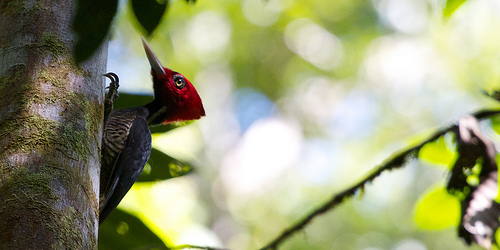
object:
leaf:
[132, 148, 198, 183]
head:
[133, 36, 206, 122]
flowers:
[440, 113, 499, 196]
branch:
[262, 107, 499, 250]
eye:
[172, 75, 185, 89]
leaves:
[411, 129, 499, 175]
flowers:
[458, 168, 499, 250]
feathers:
[96, 106, 149, 201]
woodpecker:
[95, 36, 208, 228]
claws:
[97, 73, 124, 97]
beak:
[141, 37, 164, 78]